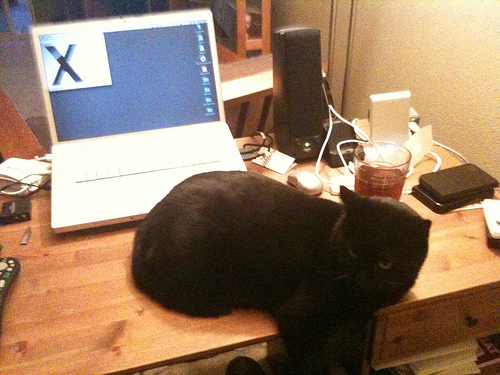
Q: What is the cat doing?
A: Sitting on the table.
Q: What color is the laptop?
A: White.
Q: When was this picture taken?
A: At night.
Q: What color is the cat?
A: Black.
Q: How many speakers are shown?
A: 2.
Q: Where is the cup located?
A: Behind the cat.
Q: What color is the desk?
A: Brown.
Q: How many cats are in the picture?
A: 1.